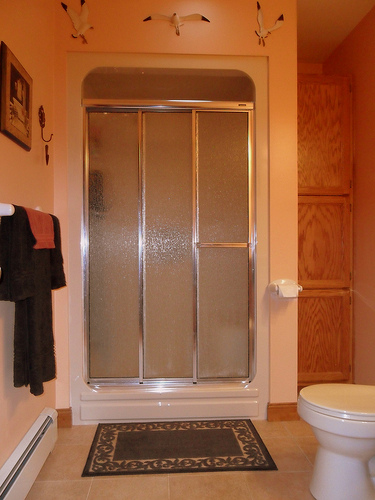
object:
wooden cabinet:
[298, 287, 352, 386]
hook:
[37, 107, 52, 143]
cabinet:
[295, 189, 353, 289]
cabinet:
[297, 56, 355, 190]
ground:
[249, 54, 302, 81]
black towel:
[0, 204, 65, 396]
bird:
[253, 1, 285, 48]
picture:
[1, 38, 34, 154]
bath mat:
[82, 417, 278, 478]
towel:
[24, 203, 57, 253]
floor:
[28, 418, 307, 497]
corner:
[37, 0, 74, 432]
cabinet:
[76, 98, 258, 431]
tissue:
[277, 285, 301, 301]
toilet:
[293, 378, 374, 499]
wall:
[101, 10, 129, 43]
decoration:
[137, 5, 212, 35]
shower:
[71, 64, 259, 395]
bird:
[134, 7, 215, 40]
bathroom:
[0, 1, 375, 498]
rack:
[0, 199, 62, 226]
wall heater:
[1, 403, 58, 497]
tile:
[26, 468, 310, 498]